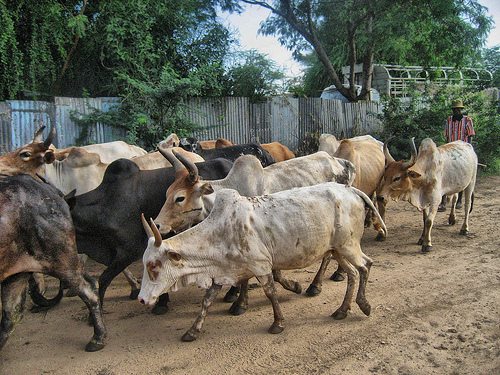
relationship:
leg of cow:
[261, 271, 290, 336] [130, 182, 392, 342]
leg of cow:
[181, 284, 220, 347] [130, 182, 392, 342]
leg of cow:
[334, 255, 357, 323] [130, 182, 392, 342]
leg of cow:
[346, 250, 382, 322] [130, 182, 392, 342]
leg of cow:
[63, 268, 113, 351] [1, 169, 112, 357]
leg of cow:
[85, 259, 126, 331] [45, 158, 249, 324]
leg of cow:
[181, 284, 221, 328] [45, 158, 249, 324]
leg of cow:
[421, 200, 442, 252] [375, 133, 481, 256]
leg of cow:
[458, 185, 477, 237] [375, 133, 481, 256]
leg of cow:
[446, 191, 458, 229] [375, 133, 481, 256]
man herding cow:
[436, 94, 477, 218] [375, 133, 481, 256]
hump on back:
[99, 154, 141, 189] [78, 152, 232, 193]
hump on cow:
[99, 154, 141, 189] [45, 158, 249, 324]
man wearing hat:
[436, 94, 477, 218] [446, 98, 468, 110]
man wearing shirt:
[436, 94, 477, 218] [445, 114, 476, 148]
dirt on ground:
[2, 165, 500, 374] [1, 157, 499, 374]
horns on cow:
[149, 217, 166, 252] [130, 182, 392, 342]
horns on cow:
[136, 212, 156, 241] [130, 182, 392, 342]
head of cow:
[130, 213, 177, 315] [130, 182, 392, 342]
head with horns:
[130, 213, 177, 315] [149, 217, 166, 252]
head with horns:
[130, 213, 177, 315] [136, 212, 156, 241]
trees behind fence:
[233, 1, 489, 106] [1, 92, 500, 210]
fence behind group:
[1, 92, 500, 210] [1, 122, 487, 354]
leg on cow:
[181, 284, 220, 347] [130, 182, 392, 342]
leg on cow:
[252, 268, 284, 326] [130, 182, 392, 342]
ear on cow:
[164, 249, 184, 264] [130, 182, 392, 342]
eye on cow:
[148, 262, 160, 274] [130, 182, 392, 342]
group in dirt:
[1, 122, 487, 354] [2, 165, 500, 374]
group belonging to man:
[1, 122, 487, 354] [436, 94, 477, 218]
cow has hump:
[45, 158, 249, 324] [99, 154, 141, 189]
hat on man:
[446, 98, 468, 110] [436, 94, 477, 218]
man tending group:
[436, 94, 477, 218] [1, 122, 487, 354]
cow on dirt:
[130, 182, 392, 342] [2, 165, 500, 374]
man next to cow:
[436, 94, 477, 218] [375, 133, 481, 256]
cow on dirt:
[375, 133, 481, 256] [2, 165, 500, 374]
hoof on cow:
[420, 236, 434, 254] [375, 133, 481, 256]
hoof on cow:
[458, 226, 470, 236] [375, 133, 481, 256]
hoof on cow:
[447, 214, 457, 227] [375, 133, 481, 256]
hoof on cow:
[416, 236, 426, 248] [375, 133, 481, 256]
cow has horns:
[133, 184, 392, 343] [136, 212, 156, 241]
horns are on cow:
[136, 212, 156, 241] [133, 184, 392, 343]